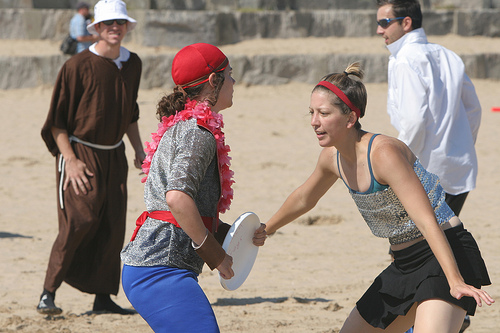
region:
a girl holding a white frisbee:
[109, 28, 279, 331]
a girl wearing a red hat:
[154, 33, 245, 122]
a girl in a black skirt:
[266, 55, 488, 321]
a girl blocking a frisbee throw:
[251, 26, 497, 331]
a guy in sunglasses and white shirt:
[357, 3, 481, 216]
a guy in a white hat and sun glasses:
[76, 0, 152, 45]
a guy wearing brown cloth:
[32, 1, 134, 323]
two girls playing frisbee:
[103, 22, 467, 329]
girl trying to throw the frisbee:
[132, 33, 273, 319]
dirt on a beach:
[241, 83, 311, 187]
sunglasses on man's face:
[368, 18, 409, 27]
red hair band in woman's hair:
[318, 82, 360, 113]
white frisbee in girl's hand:
[221, 211, 263, 295]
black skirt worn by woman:
[356, 240, 491, 323]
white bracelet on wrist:
[192, 224, 213, 254]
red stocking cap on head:
[165, 40, 234, 73]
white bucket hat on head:
[82, 0, 133, 25]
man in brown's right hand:
[60, 157, 93, 198]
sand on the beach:
[302, 244, 345, 286]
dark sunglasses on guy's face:
[100, 21, 131, 29]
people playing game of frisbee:
[126, 38, 487, 326]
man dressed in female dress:
[23, 5, 139, 325]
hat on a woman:
[77, 5, 144, 24]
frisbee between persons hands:
[214, 212, 258, 285]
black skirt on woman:
[356, 233, 491, 307]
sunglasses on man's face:
[364, 11, 412, 26]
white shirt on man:
[374, 34, 484, 194]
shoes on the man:
[34, 273, 126, 323]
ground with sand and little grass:
[14, 90, 493, 326]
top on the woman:
[322, 139, 457, 236]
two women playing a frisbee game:
[115, 34, 487, 330]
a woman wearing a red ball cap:
[155, 40, 243, 139]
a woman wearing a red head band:
[298, 56, 379, 153]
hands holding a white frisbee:
[211, 210, 270, 301]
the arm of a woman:
[372, 137, 497, 322]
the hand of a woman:
[443, 272, 494, 312]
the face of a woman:
[307, 88, 339, 149]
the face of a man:
[373, 2, 398, 52]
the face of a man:
[98, 18, 133, 47]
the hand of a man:
[60, 153, 97, 197]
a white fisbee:
[222, 214, 264, 289]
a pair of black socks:
[36, 285, 133, 314]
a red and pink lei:
[137, 103, 237, 211]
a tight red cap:
[166, 42, 227, 83]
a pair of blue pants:
[122, 268, 220, 332]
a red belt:
[128, 209, 222, 236]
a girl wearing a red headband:
[271, 55, 492, 331]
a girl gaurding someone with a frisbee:
[119, 40, 495, 331]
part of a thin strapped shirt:
[325, 135, 407, 192]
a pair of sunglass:
[377, 17, 405, 27]